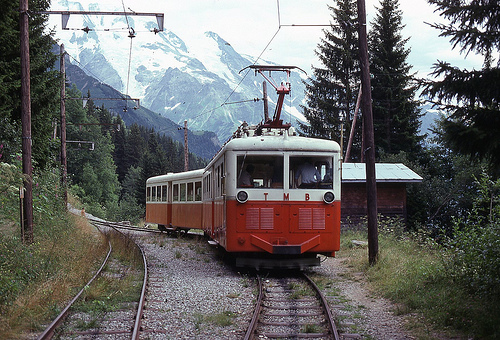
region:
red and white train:
[135, 128, 352, 277]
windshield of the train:
[232, 149, 336, 194]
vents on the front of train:
[243, 204, 333, 235]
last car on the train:
[143, 167, 173, 228]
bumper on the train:
[253, 234, 323, 254]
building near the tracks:
[302, 155, 423, 227]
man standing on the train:
[289, 159, 324, 189]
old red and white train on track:
[132, 117, 363, 269]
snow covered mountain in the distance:
[71, 7, 280, 117]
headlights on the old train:
[233, 185, 335, 205]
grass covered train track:
[73, 223, 156, 339]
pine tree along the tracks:
[372, 1, 427, 183]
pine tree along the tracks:
[426, 3, 498, 157]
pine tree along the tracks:
[81, 155, 148, 216]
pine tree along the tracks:
[28, 5, 55, 163]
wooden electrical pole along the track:
[19, 6, 43, 258]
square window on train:
[142, 179, 152, 204]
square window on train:
[144, 181, 158, 205]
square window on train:
[157, 179, 169, 201]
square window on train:
[178, 176, 189, 198]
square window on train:
[191, 171, 198, 209]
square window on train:
[234, 148, 291, 193]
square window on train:
[288, 158, 336, 189]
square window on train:
[205, 171, 216, 209]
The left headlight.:
[235, 192, 247, 200]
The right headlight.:
[321, 191, 336, 201]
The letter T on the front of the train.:
[262, 192, 267, 199]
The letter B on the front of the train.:
[302, 193, 311, 199]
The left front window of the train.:
[238, 154, 283, 188]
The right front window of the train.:
[288, 156, 333, 191]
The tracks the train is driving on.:
[247, 278, 335, 339]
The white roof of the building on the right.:
[336, 157, 418, 184]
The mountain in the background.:
[54, 0, 491, 169]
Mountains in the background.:
[52, 3, 484, 203]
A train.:
[125, 122, 355, 272]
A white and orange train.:
[141, 120, 353, 272]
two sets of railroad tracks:
[36, 213, 341, 339]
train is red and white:
[146, 80, 341, 270]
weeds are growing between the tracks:
[37, 217, 148, 339]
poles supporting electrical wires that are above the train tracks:
[16, 1, 380, 339]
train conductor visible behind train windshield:
[143, 80, 343, 278]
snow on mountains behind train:
[30, 1, 461, 273]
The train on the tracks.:
[143, 137, 345, 269]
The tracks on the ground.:
[238, 266, 343, 337]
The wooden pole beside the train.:
[357, 1, 379, 264]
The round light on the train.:
[321, 190, 336, 202]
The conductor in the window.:
[293, 158, 323, 190]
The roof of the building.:
[339, 160, 424, 181]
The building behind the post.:
[339, 160, 422, 242]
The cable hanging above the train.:
[183, 23, 282, 123]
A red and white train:
[141, 129, 358, 282]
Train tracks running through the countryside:
[254, 265, 345, 338]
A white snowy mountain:
[73, 0, 305, 157]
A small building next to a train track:
[339, 150, 430, 221]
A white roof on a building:
[343, 160, 420, 183]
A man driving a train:
[294, 157, 329, 189]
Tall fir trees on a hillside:
[11, 110, 200, 232]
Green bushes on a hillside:
[391, 170, 498, 336]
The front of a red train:
[235, 145, 339, 202]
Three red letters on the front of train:
[259, 189, 319, 206]